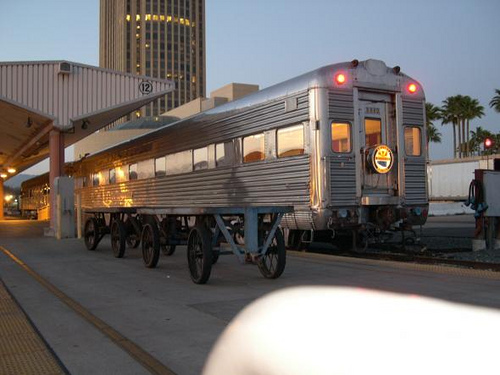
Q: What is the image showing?
A: It is showing a train station.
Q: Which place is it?
A: It is a train station.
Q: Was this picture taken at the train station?
A: Yes, it was taken in the train station.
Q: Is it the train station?
A: Yes, it is the train station.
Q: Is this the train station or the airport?
A: It is the train station.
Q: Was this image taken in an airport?
A: No, the picture was taken in a train station.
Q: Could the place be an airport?
A: No, it is a train station.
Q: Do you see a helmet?
A: No, there are no helmets.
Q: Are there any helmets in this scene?
A: No, there are no helmets.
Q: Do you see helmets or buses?
A: No, there are no helmets or buses.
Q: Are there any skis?
A: No, there are no skis.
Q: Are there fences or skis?
A: No, there are no skis or fences.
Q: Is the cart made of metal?
A: Yes, the cart is made of metal.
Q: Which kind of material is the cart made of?
A: The cart is made of metal.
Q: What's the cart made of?
A: The cart is made of metal.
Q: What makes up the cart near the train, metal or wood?
A: The cart is made of metal.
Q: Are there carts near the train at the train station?
A: Yes, there is a cart near the train.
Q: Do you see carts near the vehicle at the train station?
A: Yes, there is a cart near the train.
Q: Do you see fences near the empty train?
A: No, there is a cart near the train.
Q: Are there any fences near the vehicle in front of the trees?
A: No, there is a cart near the train.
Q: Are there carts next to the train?
A: Yes, there is a cart next to the train.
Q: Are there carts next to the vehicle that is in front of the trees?
A: Yes, there is a cart next to the train.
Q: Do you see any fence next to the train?
A: No, there is a cart next to the train.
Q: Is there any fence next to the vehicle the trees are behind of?
A: No, there is a cart next to the train.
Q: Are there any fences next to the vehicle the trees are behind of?
A: No, there is a cart next to the train.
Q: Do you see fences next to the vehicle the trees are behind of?
A: No, there is a cart next to the train.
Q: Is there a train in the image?
A: Yes, there is a train.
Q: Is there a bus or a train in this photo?
A: Yes, there is a train.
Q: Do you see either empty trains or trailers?
A: Yes, there is an empty train.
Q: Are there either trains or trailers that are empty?
A: Yes, the train is empty.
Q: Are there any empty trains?
A: Yes, there is an empty train.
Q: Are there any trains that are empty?
A: Yes, there is a train that is empty.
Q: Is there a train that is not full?
A: Yes, there is a empty train.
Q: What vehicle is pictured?
A: The vehicle is a train.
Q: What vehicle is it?
A: The vehicle is a train.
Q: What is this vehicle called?
A: This is a train.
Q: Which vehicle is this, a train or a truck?
A: This is a train.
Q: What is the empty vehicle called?
A: The vehicle is a train.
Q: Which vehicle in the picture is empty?
A: The vehicle is a train.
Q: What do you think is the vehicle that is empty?
A: The vehicle is a train.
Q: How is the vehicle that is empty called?
A: The vehicle is a train.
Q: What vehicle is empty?
A: The vehicle is a train.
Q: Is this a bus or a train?
A: This is a train.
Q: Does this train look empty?
A: Yes, the train is empty.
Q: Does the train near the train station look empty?
A: Yes, the train is empty.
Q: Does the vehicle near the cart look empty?
A: Yes, the train is empty.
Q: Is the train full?
A: No, the train is empty.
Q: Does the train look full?
A: No, the train is empty.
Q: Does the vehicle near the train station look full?
A: No, the train is empty.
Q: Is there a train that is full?
A: No, there is a train but it is empty.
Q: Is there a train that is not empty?
A: No, there is a train but it is empty.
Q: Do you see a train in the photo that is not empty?
A: No, there is a train but it is empty.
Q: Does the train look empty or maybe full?
A: The train is empty.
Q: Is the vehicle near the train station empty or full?
A: The train is empty.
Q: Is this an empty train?
A: Yes, this is an empty train.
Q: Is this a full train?
A: No, this is an empty train.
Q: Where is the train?
A: The train is at the train station.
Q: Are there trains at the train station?
A: Yes, there is a train at the train station.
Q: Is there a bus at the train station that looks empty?
A: No, there is a train at the train station.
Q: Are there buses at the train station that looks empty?
A: No, there is a train at the train station.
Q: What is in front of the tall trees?
A: The train is in front of the trees.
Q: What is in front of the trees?
A: The train is in front of the trees.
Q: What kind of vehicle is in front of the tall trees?
A: The vehicle is a train.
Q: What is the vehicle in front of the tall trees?
A: The vehicle is a train.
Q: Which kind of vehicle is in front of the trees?
A: The vehicle is a train.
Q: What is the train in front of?
A: The train is in front of the trees.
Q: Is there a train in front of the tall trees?
A: Yes, there is a train in front of the trees.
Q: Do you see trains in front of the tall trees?
A: Yes, there is a train in front of the trees.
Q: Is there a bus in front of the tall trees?
A: No, there is a train in front of the trees.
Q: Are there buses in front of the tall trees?
A: No, there is a train in front of the trees.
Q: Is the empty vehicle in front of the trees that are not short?
A: Yes, the train is in front of the trees.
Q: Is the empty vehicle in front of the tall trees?
A: Yes, the train is in front of the trees.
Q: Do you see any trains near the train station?
A: Yes, there is a train near the train station.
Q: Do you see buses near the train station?
A: No, there is a train near the train station.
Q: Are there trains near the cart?
A: Yes, there is a train near the cart.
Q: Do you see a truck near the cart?
A: No, there is a train near the cart.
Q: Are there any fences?
A: No, there are no fences.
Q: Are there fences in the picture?
A: No, there are no fences.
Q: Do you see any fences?
A: No, there are no fences.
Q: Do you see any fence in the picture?
A: No, there are no fences.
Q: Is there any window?
A: Yes, there is a window.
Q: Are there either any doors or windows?
A: Yes, there is a window.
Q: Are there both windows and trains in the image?
A: Yes, there are both a window and a train.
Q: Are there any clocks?
A: No, there are no clocks.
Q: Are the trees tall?
A: Yes, the trees are tall.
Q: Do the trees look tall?
A: Yes, the trees are tall.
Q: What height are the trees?
A: The trees are tall.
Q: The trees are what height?
A: The trees are tall.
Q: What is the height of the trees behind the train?
A: The trees are tall.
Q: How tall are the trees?
A: The trees are tall.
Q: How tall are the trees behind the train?
A: The trees are tall.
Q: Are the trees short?
A: No, the trees are tall.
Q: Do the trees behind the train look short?
A: No, the trees are tall.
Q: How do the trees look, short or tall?
A: The trees are tall.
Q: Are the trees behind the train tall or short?
A: The trees are tall.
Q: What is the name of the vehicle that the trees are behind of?
A: The vehicle is a train.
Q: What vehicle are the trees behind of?
A: The trees are behind the train.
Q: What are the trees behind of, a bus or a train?
A: The trees are behind a train.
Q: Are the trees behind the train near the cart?
A: Yes, the trees are behind the train.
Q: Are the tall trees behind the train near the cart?
A: Yes, the trees are behind the train.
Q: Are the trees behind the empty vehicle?
A: Yes, the trees are behind the train.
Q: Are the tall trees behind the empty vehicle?
A: Yes, the trees are behind the train.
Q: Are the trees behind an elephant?
A: No, the trees are behind the train.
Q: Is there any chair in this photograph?
A: No, there are no chairs.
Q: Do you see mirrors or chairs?
A: No, there are no chairs or mirrors.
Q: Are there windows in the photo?
A: Yes, there is a window.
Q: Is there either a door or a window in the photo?
A: Yes, there is a window.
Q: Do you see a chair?
A: No, there are no chairs.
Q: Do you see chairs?
A: No, there are no chairs.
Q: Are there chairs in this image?
A: No, there are no chairs.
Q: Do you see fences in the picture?
A: No, there are no fences.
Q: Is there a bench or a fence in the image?
A: No, there are no fences or benches.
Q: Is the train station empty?
A: Yes, the train station is empty.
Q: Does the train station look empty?
A: Yes, the train station is empty.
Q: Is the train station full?
A: No, the train station is empty.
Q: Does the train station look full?
A: No, the train station is empty.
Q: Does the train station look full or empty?
A: The train station is empty.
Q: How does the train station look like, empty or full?
A: The train station is empty.